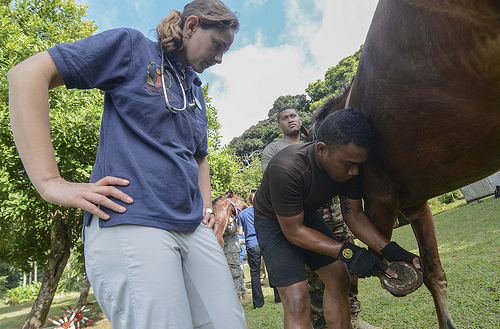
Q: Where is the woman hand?
A: On hips.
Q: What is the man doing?
A: Inspecting horse hoof.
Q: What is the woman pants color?
A: Light gray.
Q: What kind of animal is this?
A: Horse.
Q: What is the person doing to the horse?
A: Fitting the horses shoe.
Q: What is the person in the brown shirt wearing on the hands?
A: Gloves.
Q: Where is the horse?
A: Green field.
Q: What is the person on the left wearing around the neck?
A: Stethoscope.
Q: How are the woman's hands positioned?
A: On the hips.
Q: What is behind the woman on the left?
A: Trees.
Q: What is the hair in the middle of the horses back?
A: Mane.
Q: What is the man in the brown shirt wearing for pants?
A: Shorts.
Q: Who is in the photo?
A: Some people.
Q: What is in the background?
A: Trees.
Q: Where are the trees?
A: Behind the people.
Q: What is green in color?
A: The grass.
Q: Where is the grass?
A: Below the people.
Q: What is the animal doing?
A: Standing.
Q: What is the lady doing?
A: Standing.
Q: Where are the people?
A: Outside somewhere.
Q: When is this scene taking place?
A: Daytime.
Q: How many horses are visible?
A: Two.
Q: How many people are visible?
A: Five.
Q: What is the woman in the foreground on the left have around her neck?
A: Stethoscope.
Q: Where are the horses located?
A: Field.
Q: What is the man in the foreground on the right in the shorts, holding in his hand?
A: The horse's hoof.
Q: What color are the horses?
A: Brown.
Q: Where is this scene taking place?
A: At a farm for horses.